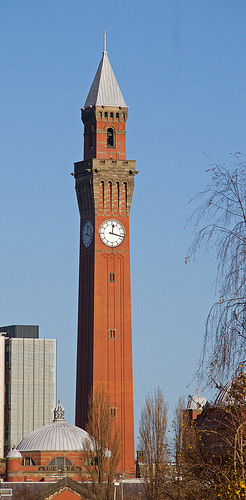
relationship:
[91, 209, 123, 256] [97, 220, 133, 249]
clock in tower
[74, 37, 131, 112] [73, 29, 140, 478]
peak of tower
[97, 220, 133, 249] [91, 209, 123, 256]
face of clock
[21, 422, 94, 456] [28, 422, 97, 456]
building in round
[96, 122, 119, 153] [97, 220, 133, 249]
window in tower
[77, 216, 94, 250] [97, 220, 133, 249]
clock in tower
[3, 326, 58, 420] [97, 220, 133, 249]
building near tower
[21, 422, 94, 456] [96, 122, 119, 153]
building has window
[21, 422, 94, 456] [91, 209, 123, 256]
building has clock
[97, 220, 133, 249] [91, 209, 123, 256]
tower has clock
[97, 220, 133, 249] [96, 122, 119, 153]
tower has window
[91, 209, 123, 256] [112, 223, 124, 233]
clock has numbers